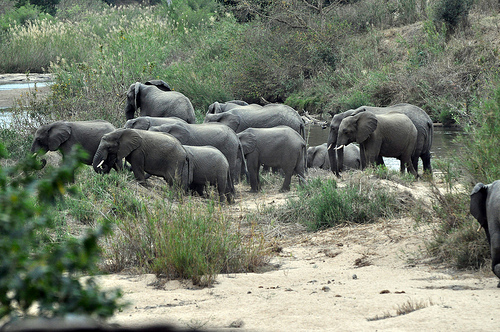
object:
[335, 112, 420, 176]
elephant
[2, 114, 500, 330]
field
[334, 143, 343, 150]
tusk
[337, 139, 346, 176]
trunk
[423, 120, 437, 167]
tail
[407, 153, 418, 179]
leg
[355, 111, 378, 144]
ear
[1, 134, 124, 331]
bush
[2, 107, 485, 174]
water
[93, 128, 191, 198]
elephants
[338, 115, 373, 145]
head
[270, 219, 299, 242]
stick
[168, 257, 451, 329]
sand